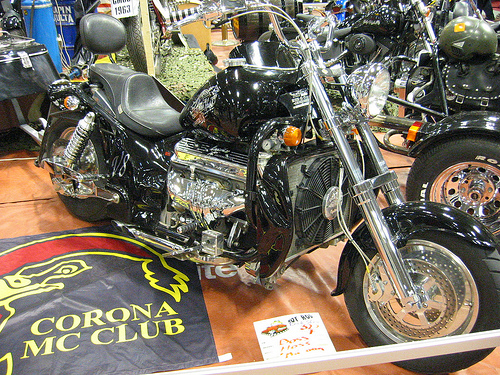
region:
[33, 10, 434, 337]
Black motorcycle at a show.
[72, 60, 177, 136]
Old grey leather seat.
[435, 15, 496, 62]
Green helmet on the next motorcycle.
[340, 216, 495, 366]
Black front wheel.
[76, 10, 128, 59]
Old grey leather backrest.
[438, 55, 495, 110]
Black leather cover seat.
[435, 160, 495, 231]
Shiny silver wheel cover.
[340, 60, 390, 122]
Silver headlight.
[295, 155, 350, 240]
The front ventilation is black.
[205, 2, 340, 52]
The handlebars are made of shiny silver.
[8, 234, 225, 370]
A flag from a motorcycle club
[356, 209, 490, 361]
Front wheel of a motorcycle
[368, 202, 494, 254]
Fender on the wheel of motorcycle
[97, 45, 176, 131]
The seat on a motorcycle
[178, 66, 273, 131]
The gas tank on a motorcycle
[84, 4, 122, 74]
Back rest on motorcycle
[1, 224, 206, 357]
The flag is on the floor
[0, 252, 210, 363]
The flag is black red and yellow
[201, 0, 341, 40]
Handlebar and brake of motorcycle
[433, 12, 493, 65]
An army green colored helmet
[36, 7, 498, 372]
A large black motorcycle.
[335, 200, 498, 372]
The front wheel of the motorcycle.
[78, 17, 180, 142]
The seat on the motorcycle.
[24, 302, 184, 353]
Yellow words on the ground.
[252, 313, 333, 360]
A piece of paper on the ground.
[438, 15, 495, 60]
A dark green helmet.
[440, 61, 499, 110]
A black leather bag.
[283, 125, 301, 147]
The light on the motorcycle.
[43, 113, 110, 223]
The back wheel of the motorcycle.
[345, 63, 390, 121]
The front headlight.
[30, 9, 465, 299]
Bike on the ground.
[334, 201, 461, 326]
Wheel on the bike.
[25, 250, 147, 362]
Logo on the floor.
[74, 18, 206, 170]
Seat on the bike.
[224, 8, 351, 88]
Handle on the bike.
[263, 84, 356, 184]
Lights on the bike.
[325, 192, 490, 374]
Black wheel on the bike.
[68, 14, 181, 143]
Black leather seat on the bike.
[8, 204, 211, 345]
Yellow and red logo.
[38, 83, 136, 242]
Back wheel on the bike.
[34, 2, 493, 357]
motorcycle on display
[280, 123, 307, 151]
orange reflector on the bike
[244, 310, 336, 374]
white sign with red writing on it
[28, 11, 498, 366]
shiny silver on the motorbike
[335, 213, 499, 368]
silver and black wheel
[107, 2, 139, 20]
black writing on a white sign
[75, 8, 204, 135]
black seat on the bike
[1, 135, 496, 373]
floor is burnt orange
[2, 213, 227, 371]
yellow and red logo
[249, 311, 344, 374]
sign laying on the floor